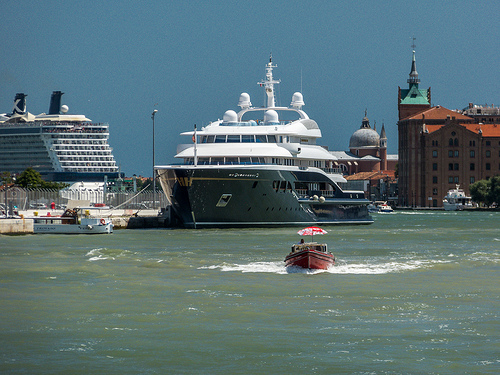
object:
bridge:
[181, 125, 285, 141]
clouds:
[86, 98, 94, 102]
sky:
[2, 2, 497, 150]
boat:
[442, 184, 472, 211]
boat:
[368, 201, 395, 214]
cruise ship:
[1, 89, 126, 209]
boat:
[284, 226, 335, 273]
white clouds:
[88, 36, 170, 100]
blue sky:
[0, 0, 497, 177]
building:
[398, 32, 500, 208]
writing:
[229, 172, 259, 177]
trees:
[16, 164, 45, 189]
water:
[4, 210, 496, 373]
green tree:
[466, 178, 496, 209]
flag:
[192, 121, 198, 167]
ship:
[0, 86, 124, 187]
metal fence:
[0, 186, 172, 212]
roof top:
[396, 37, 432, 105]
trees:
[468, 168, 500, 210]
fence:
[0, 186, 170, 209]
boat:
[153, 52, 374, 230]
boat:
[34, 206, 115, 234]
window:
[242, 135, 255, 143]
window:
[227, 134, 240, 142]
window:
[215, 134, 225, 143]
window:
[256, 135, 267, 142]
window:
[204, 135, 214, 143]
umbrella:
[298, 226, 328, 237]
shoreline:
[2, 185, 498, 214]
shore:
[0, 180, 498, 210]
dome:
[349, 108, 383, 147]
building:
[324, 108, 398, 209]